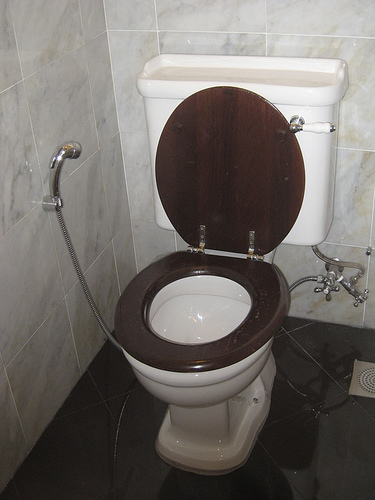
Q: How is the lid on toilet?
A: Up.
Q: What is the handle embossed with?
A: White enamel.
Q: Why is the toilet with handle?
A: To flush.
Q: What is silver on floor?
A: Drain hole.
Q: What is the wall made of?
A: Marble.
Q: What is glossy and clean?
A: Toilet bowl.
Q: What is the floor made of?
A: Tiles.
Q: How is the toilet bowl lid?
A: Up.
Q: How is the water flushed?
A: With a handle on the right side of the tank.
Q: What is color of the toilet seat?
A: Brown.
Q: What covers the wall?
A: Tiles.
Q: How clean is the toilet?
A: Very clean.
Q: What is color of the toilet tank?
A: White.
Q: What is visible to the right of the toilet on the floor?
A: The drain.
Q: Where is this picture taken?
A: Bathroom.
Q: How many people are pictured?
A: None.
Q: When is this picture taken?
A: Daytime.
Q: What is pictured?
A: Toilet.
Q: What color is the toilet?
A: White.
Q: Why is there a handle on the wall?
A: Water faucet.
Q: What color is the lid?
A: Wood.